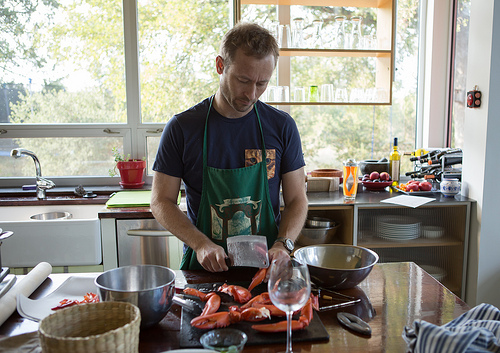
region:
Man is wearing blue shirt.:
[151, 99, 313, 254]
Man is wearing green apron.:
[178, 85, 294, 277]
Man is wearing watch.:
[268, 235, 302, 260]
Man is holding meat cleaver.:
[204, 226, 279, 281]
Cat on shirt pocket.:
[241, 145, 281, 185]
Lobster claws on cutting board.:
[180, 256, 330, 351]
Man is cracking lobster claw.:
[191, 227, 293, 299]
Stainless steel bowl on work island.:
[288, 226, 380, 291]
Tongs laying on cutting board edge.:
[168, 273, 208, 320]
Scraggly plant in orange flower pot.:
[100, 148, 152, 193]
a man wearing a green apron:
[193, 28, 276, 244]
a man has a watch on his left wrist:
[271, 232, 296, 257]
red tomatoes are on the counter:
[397, 176, 432, 194]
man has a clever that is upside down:
[195, 230, 271, 270]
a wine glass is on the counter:
[267, 253, 307, 349]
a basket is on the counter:
[36, 301, 141, 349]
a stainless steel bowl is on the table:
[292, 241, 377, 291]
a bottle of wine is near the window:
[387, 135, 398, 185]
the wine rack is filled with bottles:
[401, 145, 461, 182]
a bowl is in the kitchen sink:
[0, 200, 101, 262]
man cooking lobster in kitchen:
[155, 5, 399, 335]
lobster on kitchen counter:
[176, 270, 318, 334]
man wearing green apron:
[163, 63, 328, 243]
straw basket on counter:
[45, 296, 146, 348]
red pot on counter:
[104, 150, 147, 187]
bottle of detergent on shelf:
[334, 156, 364, 199]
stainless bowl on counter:
[292, 228, 381, 301]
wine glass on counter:
[267, 247, 304, 350]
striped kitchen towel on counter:
[410, 312, 498, 349]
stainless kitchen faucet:
[7, 133, 50, 203]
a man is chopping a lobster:
[143, 16, 320, 340]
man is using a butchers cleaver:
[148, 20, 311, 276]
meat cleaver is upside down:
[217, 228, 275, 270]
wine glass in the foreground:
[260, 250, 315, 352]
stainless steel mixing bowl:
[93, 263, 177, 329]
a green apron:
[179, 85, 284, 276]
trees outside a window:
[1, 0, 419, 170]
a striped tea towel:
[399, 300, 498, 351]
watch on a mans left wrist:
[272, 234, 299, 254]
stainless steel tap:
[8, 144, 55, 201]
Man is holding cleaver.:
[196, 234, 275, 277]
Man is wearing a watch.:
[273, 234, 297, 256]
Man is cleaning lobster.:
[190, 254, 317, 337]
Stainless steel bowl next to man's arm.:
[288, 233, 379, 295]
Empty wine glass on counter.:
[264, 255, 318, 351]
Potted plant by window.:
[104, 133, 154, 191]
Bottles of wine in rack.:
[398, 145, 464, 191]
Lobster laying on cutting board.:
[176, 271, 331, 351]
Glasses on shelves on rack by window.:
[227, 2, 408, 107]